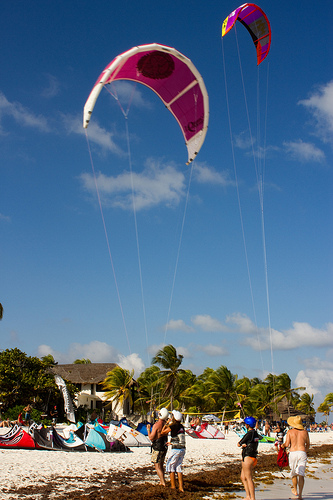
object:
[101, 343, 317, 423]
trees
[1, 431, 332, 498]
sand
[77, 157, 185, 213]
cloud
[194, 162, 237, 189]
cloud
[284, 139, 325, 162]
cloud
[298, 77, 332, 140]
cloud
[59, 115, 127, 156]
cloud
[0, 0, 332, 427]
sky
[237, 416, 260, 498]
woman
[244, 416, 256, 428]
helmet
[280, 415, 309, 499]
man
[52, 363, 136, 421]
house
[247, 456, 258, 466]
bikini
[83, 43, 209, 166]
kite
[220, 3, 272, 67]
kite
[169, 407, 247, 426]
net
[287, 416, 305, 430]
hat